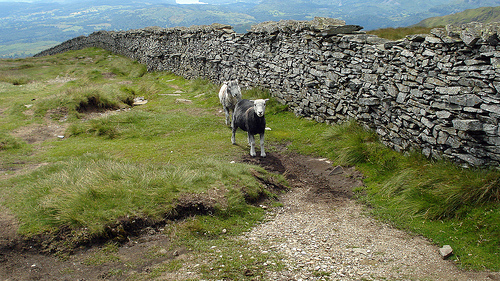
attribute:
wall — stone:
[37, 21, 498, 161]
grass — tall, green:
[1, 0, 498, 280]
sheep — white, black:
[232, 102, 272, 155]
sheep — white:
[216, 74, 242, 122]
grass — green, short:
[436, 222, 466, 240]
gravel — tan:
[155, 175, 499, 279]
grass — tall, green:
[381, 131, 498, 239]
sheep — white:
[228, 95, 272, 159]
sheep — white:
[215, 75, 245, 127]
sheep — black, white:
[220, 100, 290, 158]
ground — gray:
[394, 110, 469, 162]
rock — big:
[425, 239, 457, 259]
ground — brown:
[248, 136, 355, 278]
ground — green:
[0, 46, 499, 279]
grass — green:
[363, 25, 443, 37]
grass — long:
[312, 119, 497, 224]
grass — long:
[243, 87, 288, 114]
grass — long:
[189, 74, 216, 96]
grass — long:
[135, 62, 151, 79]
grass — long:
[81, 45, 108, 55]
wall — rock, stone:
[31, 13, 498, 170]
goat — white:
[215, 74, 245, 125]